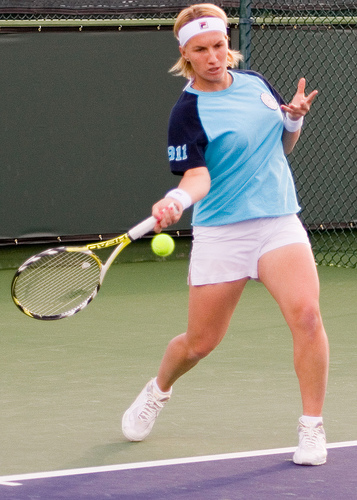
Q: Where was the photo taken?
A: At a tennis court.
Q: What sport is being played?
A: Tennis.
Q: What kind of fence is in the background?
A: Chain link.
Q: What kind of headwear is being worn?
A: A headband.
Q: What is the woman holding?
A: A tennis racket.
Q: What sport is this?
A: Tennis.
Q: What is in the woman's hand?
A: A racquet.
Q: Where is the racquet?
A: In the woman's hand.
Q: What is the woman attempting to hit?
A: The ball.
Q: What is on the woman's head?
A: A headband.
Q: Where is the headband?
A: Around the woman's head.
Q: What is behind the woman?
A: A fence.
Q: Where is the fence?
A: Behind the woman.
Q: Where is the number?
A: On the woman's shirt.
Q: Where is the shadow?
A: On the court.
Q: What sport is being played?
A: Tennis.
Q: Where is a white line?
A: On the court.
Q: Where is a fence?
A: Behind the player.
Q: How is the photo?
A: Clear.